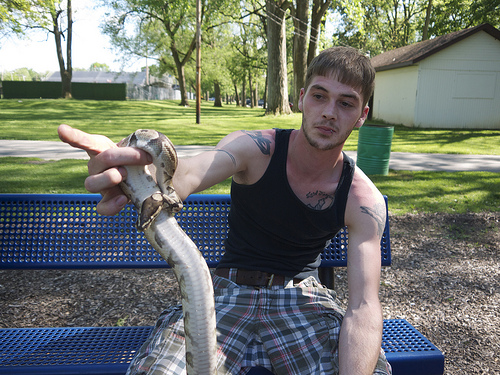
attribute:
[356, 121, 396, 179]
garbage can — green, for trashed things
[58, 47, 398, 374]
man — holding the snake, holding a snake, sitting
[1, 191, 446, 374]
park bench — blue, blue in color, made of many parts, made of metal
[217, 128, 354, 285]
tank top — black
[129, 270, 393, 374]
shorts — plaid, designed in plaid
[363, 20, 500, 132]
building — in the park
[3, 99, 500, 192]
grass — green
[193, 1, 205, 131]
pole — for utility purpose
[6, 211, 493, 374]
soil insulator — brown, on the ground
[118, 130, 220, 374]
snake — a python, on hold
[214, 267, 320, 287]
belt — brown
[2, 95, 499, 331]
lawn — made of many section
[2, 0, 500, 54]
leaves — green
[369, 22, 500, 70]
roof — brow